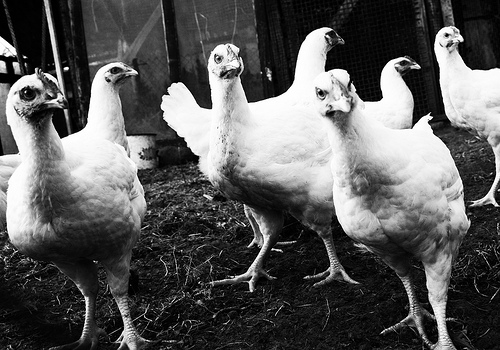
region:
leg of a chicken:
[70, 277, 98, 348]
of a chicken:
[116, 286, 156, 336]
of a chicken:
[307, 236, 357, 293]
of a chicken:
[387, 266, 424, 336]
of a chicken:
[422, 273, 465, 338]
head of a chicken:
[11, 61, 69, 134]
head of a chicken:
[210, 28, 254, 76]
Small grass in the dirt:
[153, 234, 182, 278]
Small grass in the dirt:
[182, 226, 204, 249]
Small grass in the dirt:
[314, 291, 329, 333]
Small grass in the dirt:
[265, 275, 299, 325]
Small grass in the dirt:
[196, 301, 263, 331]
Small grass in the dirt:
[33, 275, 62, 314]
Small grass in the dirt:
[471, 244, 497, 301]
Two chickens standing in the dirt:
[5, 41, 177, 335]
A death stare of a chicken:
[10, 62, 72, 147]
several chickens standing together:
[7, 39, 499, 343]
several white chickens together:
[6, 32, 483, 337]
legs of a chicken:
[211, 209, 393, 316]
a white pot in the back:
[126, 127, 176, 195]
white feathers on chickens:
[158, 104, 478, 269]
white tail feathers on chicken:
[143, 65, 209, 162]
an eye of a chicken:
[11, 75, 50, 118]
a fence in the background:
[98, 47, 268, 141]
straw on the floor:
[94, 202, 490, 349]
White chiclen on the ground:
[428, 18, 496, 135]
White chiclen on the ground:
[300, 76, 457, 303]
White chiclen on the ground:
[356, 40, 434, 127]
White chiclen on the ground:
[204, 46, 311, 268]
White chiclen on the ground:
[270, 14, 342, 96]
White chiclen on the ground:
[6, 66, 161, 321]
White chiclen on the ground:
[46, 32, 173, 176]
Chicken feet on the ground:
[40, 314, 172, 349]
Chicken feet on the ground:
[183, 230, 350, 303]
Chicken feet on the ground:
[374, 305, 457, 343]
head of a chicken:
[5, 61, 62, 124]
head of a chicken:
[97, 53, 159, 82]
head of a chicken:
[203, 42, 252, 86]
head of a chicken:
[306, 24, 340, 53]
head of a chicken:
[306, 65, 357, 133]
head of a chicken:
[385, 51, 426, 86]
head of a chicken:
[418, 16, 472, 61]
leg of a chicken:
[71, 270, 96, 332]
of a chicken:
[109, 273, 149, 340]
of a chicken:
[226, 228, 287, 290]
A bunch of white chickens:
[0, 13, 495, 346]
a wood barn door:
[77, 0, 169, 139]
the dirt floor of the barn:
[1, 123, 498, 349]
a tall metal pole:
[42, 0, 72, 135]